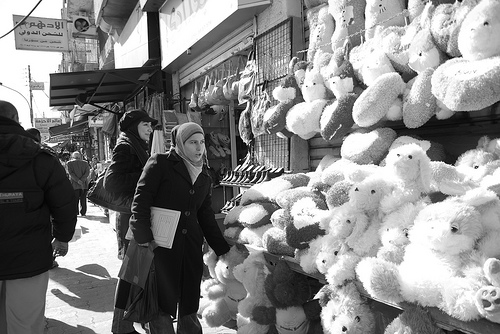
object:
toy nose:
[354, 187, 360, 191]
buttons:
[180, 229, 189, 234]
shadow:
[49, 252, 129, 315]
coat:
[0, 121, 76, 281]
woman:
[103, 107, 159, 260]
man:
[0, 100, 78, 333]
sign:
[12, 14, 86, 52]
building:
[59, 0, 336, 220]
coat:
[101, 132, 231, 321]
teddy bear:
[317, 290, 377, 334]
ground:
[24, 178, 240, 332]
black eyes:
[318, 178, 385, 288]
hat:
[118, 109, 159, 132]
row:
[257, 0, 499, 141]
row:
[222, 131, 499, 324]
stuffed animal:
[204, 0, 493, 334]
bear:
[252, 271, 321, 331]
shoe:
[222, 164, 284, 184]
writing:
[17, 16, 67, 49]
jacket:
[0, 117, 78, 281]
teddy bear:
[354, 185, 497, 324]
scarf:
[171, 122, 204, 185]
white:
[359, 189, 487, 306]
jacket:
[114, 150, 231, 319]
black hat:
[110, 110, 162, 143]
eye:
[352, 316, 364, 323]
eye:
[327, 310, 339, 327]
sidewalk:
[40, 212, 113, 326]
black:
[172, 181, 226, 257]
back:
[87, 176, 136, 214]